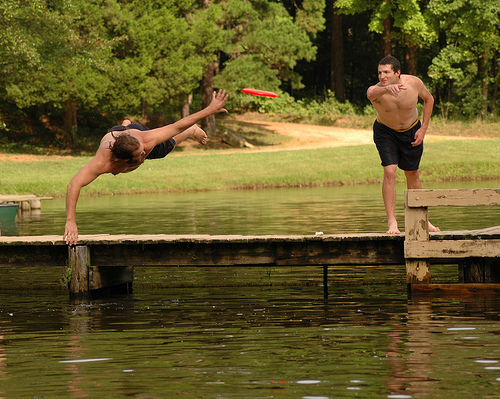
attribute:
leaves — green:
[268, 21, 281, 66]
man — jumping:
[57, 76, 235, 249]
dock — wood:
[263, 232, 378, 276]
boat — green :
[0, 202, 19, 222]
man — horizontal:
[64, 100, 266, 224]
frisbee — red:
[231, 75, 287, 118]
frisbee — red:
[217, 77, 292, 102]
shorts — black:
[367, 117, 429, 172]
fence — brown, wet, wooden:
[404, 190, 499, 262]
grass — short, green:
[298, 139, 378, 176]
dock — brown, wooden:
[16, 225, 478, 301]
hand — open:
[210, 86, 231, 113]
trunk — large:
[322, 0, 342, 107]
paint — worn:
[408, 187, 498, 278]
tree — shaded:
[322, 0, 353, 113]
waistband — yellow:
[370, 116, 422, 136]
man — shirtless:
[366, 55, 446, 238]